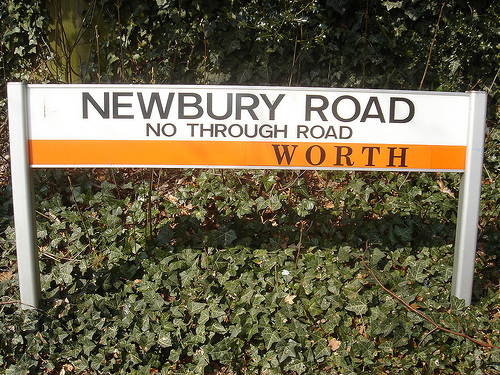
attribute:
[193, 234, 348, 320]
clovers — greenery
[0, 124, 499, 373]
ivy — Green , ground cover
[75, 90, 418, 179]
text — black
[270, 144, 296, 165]
letter — black 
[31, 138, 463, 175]
strip — orange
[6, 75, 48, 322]
pole — white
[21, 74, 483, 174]
sign — White , orange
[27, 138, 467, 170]
backdrop — orange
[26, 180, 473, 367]
leaves — green, plant leaves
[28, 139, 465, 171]
stripe — Orange 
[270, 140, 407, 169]
word — black, worth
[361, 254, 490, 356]
twigs — bare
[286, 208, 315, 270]
twigs — bare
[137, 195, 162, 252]
twigs — bare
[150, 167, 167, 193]
twigs — bare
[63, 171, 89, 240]
twigs — bare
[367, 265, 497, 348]
branch — long, thin, brown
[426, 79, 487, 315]
pole — silver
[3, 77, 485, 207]
sign — white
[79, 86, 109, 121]
letters — black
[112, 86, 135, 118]
letters — black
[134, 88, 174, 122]
letters — black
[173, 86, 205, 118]
letters — black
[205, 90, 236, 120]
letters — black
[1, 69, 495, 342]
sign — orange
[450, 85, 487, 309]
right pole — White 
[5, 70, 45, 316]
stake — wooden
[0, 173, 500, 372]
leaves — green 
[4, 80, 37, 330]
pole — White 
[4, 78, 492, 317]
sign — White , orange , newberry road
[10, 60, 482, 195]
sign — white, orange, black 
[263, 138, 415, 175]
word — black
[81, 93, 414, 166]
writing — black